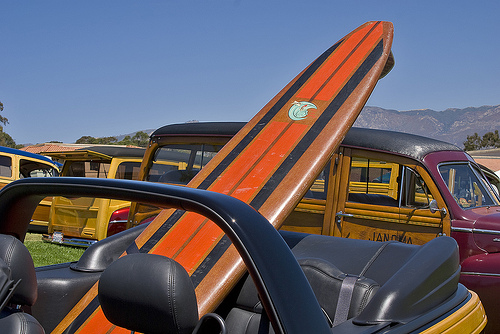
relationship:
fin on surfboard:
[378, 51, 395, 78] [40, 16, 395, 332]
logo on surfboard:
[276, 89, 327, 136] [40, 16, 395, 332]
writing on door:
[366, 229, 413, 248] [333, 144, 450, 245]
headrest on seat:
[123, 249, 187, 286] [97, 254, 204, 331]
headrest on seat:
[123, 249, 187, 286] [2, 226, 44, 332]